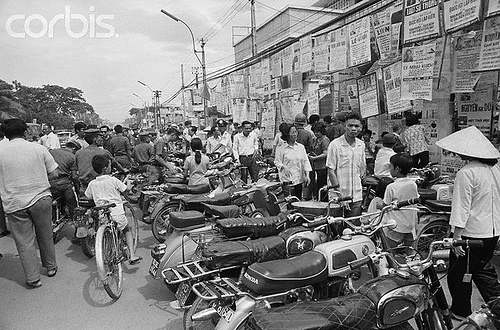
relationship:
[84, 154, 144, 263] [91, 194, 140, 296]
boy riding bicycle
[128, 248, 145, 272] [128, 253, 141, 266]
flip flop on foot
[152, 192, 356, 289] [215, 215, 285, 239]
motorcycle has moped's seat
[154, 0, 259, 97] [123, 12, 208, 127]
wires on a poles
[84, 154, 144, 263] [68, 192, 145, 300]
boy standing on bicycle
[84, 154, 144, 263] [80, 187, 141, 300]
boy riding bicycle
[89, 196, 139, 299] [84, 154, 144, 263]
bicycle underneath boy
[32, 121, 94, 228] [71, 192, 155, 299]
boy near bicycle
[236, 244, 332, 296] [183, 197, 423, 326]
seat of a motorcycle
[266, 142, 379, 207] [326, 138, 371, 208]
shirts for torso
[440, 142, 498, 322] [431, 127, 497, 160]
man has hat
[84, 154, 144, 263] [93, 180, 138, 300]
boy on bicycle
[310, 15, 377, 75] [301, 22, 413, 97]
papers on on wall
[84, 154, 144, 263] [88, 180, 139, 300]
boy on bicycle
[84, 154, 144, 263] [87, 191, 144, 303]
boy on bicycle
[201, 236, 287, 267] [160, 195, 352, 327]
moped's seat on motorcycle